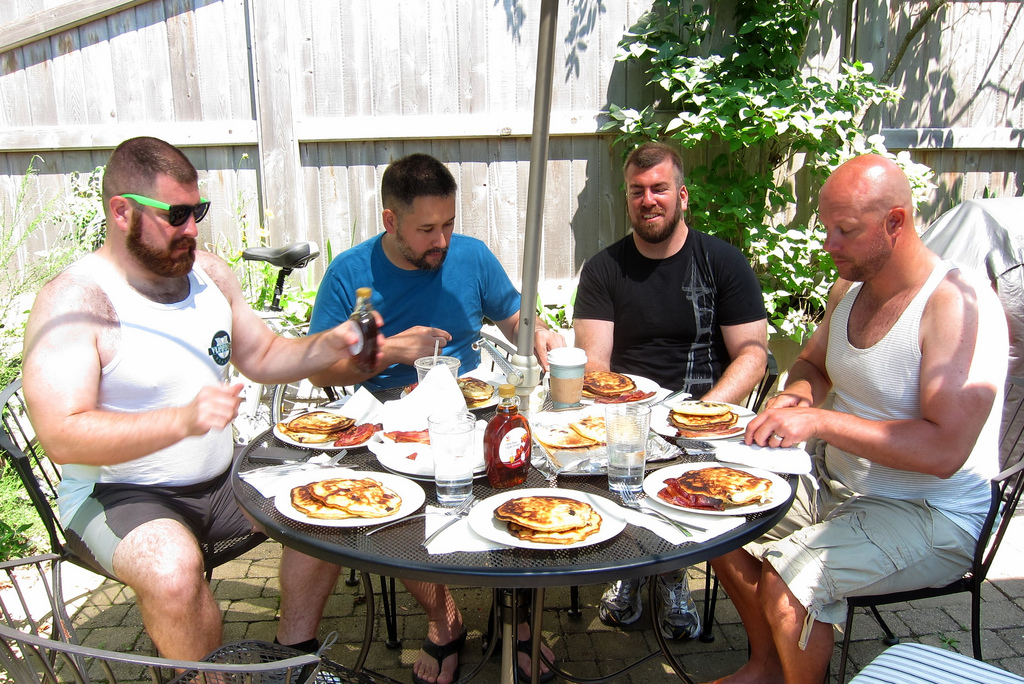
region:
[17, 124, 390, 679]
a person is sitting down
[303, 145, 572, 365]
a person is sitting down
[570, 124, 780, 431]
a person is sitting down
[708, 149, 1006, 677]
a person is sitting down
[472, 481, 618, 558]
a plate made for dining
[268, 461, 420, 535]
a plate made for dining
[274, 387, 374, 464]
a plate made for dining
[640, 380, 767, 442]
a plate made for dining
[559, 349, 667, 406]
a plate made for dining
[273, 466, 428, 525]
a plate of pancakes on a plate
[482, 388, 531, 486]
a jar of syrup on a table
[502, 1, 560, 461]
an umbrella pole on a table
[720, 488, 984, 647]
a pair of cargo shorts on a man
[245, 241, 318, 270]
a bicycle seat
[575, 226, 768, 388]
a black t-shirt on a man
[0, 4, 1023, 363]
a wooden privacy fence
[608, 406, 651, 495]
a half full glass of water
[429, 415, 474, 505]
a half full glass of water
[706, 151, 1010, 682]
the bald man is sitting down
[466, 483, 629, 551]
the pancakes on the plate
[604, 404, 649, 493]
the tall clear glass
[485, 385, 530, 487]
the bottle of syrup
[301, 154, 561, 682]
the man is wearing a blue shirt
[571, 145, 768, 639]
the man is wearing a black shirt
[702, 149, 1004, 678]
the man is wearing a tanktop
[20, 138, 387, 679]
the man is wearing sunglasses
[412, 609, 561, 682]
the slippers are black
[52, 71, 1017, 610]
the men are eating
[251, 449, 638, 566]
the plates are white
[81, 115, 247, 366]
the man is wearing sunglasses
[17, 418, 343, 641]
the man is wearing shorts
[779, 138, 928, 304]
the man has a bald head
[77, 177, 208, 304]
the man has a beard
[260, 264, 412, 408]
the man is holding a bottle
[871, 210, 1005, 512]
the sun is on the man's back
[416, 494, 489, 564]
A FORK ON A NAPKIN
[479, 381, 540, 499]
A BOTTLE OF MAPLE SYRUP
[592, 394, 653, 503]
A GLASS OF WATER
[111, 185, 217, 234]
A PAIR OF SUNGLASSES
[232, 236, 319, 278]
A BLACK BIKE SEAT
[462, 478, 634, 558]
A STACK OF PANCAKES ON A PLATE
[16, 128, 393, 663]
A MAN HOLDING A BOTTLE OF SYRUP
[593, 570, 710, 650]
A PAIR OF GYM SHOES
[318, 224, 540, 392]
A BLUE TEE SHIRT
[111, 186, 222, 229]
green and black sunshades on man's face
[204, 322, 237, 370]
green and white emblem on tee shirt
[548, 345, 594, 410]
paper cup with plastic lid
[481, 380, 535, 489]
container full of pancake syrup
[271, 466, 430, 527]
one of many plates full of pancakes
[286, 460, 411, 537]
plate of pancakes on the table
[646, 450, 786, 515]
plate of pancakes on the table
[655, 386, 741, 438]
plate of pancakes on the table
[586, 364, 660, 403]
plate of pancakes on the table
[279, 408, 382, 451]
plate of pancakes on the table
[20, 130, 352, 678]
man in a white shirt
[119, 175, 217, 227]
green colored sunglasses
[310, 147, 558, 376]
man in a blue colored shirt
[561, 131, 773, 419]
man in a black colored shirt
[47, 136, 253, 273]
A man with green and black glasses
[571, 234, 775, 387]
A man with a black shirt on